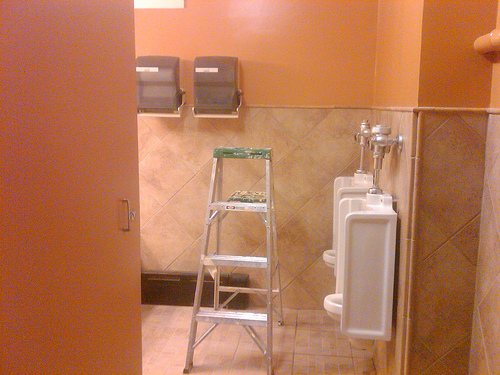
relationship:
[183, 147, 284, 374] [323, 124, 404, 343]
ladder in front of urinal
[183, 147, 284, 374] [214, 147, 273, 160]
ladder has top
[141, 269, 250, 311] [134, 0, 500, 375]
object against wall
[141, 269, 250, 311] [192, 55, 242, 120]
object under towel dispenser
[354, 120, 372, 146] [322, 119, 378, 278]
flusher above urinal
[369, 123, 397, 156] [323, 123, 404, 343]
flusher above urinal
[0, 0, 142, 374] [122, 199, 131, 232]
door has handle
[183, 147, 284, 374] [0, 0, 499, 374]
ladder in bathroom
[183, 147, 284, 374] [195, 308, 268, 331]
ladder has first rung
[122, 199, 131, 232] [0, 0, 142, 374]
handle on door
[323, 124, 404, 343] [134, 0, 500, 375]
urinal hanging on wall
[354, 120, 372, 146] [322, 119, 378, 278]
flusher on top of urinal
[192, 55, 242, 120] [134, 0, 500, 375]
towel dispenser attached to wall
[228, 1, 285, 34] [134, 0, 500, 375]
light shining on wall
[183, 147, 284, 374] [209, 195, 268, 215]
ladder has top rung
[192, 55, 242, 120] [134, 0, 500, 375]
towel dispenser hanging on wall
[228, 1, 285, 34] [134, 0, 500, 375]
light reflecting on wall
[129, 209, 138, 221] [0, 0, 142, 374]
lock on door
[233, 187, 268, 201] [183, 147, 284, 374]
paint on ladder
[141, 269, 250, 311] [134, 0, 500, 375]
object along wall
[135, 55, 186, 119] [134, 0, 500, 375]
towel dispenser on wall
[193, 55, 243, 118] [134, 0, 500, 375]
towel dispenser on wall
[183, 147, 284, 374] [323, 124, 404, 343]
ladder to left of urinal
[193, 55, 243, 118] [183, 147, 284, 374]
towel dispenser near ladder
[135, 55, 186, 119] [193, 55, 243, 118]
towel dispenser to left of towel dispenser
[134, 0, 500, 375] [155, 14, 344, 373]
tile on wall